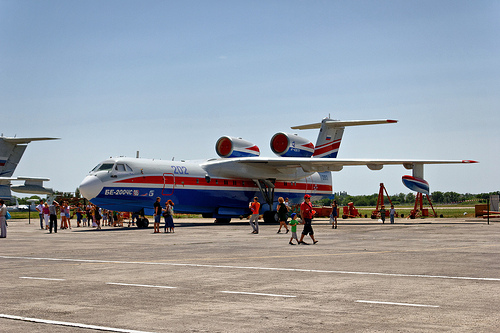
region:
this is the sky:
[147, 11, 197, 32]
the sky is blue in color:
[271, 17, 353, 58]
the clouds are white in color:
[104, 120, 165, 140]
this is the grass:
[447, 206, 457, 213]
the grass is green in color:
[447, 208, 456, 214]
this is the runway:
[143, 267, 300, 313]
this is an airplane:
[76, 116, 476, 202]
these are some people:
[41, 188, 396, 248]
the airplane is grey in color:
[148, 163, 165, 170]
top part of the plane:
[288, 110, 421, 129]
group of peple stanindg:
[38, 174, 490, 280]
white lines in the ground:
[176, 264, 428, 324]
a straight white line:
[48, 247, 498, 284]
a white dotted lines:
[36, 270, 493, 326]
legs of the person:
[296, 228, 336, 243]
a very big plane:
[46, 148, 444, 238]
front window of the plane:
[82, 164, 128, 173]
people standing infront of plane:
[31, 187, 130, 236]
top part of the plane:
[232, 128, 343, 159]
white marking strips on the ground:
[4, 217, 495, 332]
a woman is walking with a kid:
[286, 195, 319, 249]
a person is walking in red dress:
[299, 189, 320, 244]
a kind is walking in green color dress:
[288, 210, 301, 243]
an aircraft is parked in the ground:
[74, 113, 479, 225]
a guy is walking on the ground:
[179, 195, 262, 330]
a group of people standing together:
[149, 189, 179, 236]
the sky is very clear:
[4, 7, 499, 115]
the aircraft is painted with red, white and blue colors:
[75, 115, 480, 224]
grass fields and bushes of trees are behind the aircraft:
[9, 116, 499, 216]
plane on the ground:
[71, 70, 432, 242]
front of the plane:
[61, 150, 156, 217]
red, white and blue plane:
[112, 149, 215, 216]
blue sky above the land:
[81, 31, 237, 94]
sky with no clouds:
[32, 17, 162, 64]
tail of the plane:
[290, 100, 389, 158]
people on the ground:
[211, 183, 352, 272]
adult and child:
[272, 183, 337, 269]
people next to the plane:
[28, 196, 90, 241]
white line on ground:
[207, 273, 298, 330]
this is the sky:
[141, 10, 249, 86]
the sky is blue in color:
[202, 23, 281, 56]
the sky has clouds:
[122, 109, 189, 149]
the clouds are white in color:
[118, 96, 190, 145]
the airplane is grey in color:
[138, 162, 155, 168]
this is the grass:
[443, 206, 460, 216]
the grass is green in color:
[440, 208, 461, 215]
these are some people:
[41, 203, 373, 233]